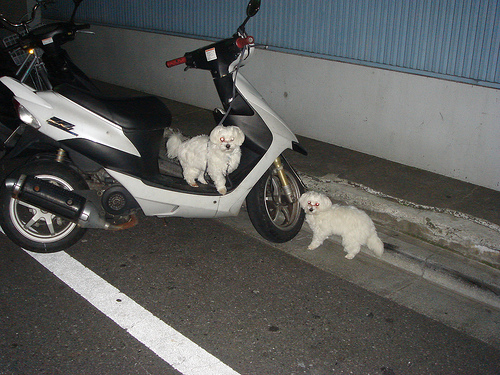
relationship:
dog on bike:
[164, 127, 242, 196] [2, 2, 301, 252]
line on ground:
[1, 225, 244, 374] [2, 178, 499, 372]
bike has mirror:
[2, 2, 301, 252] [235, 22, 246, 39]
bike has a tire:
[2, 2, 301, 252] [4, 164, 86, 252]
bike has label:
[2, 2, 301, 252] [46, 110, 79, 141]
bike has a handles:
[2, 2, 301, 252] [164, 36, 256, 70]